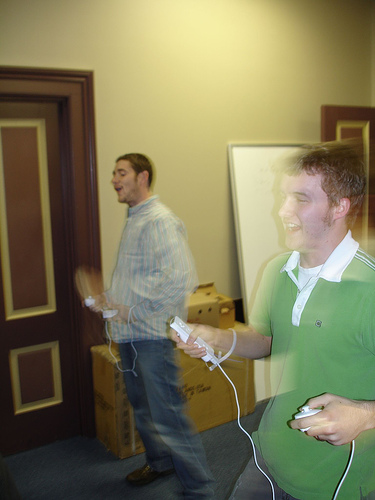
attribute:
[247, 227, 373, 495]
polo shirt — green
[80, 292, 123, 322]
controller — Wii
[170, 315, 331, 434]
controller — Wii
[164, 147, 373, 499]
man — young, smiling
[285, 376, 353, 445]
controller — wii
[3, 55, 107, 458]
door — interior , Dark colored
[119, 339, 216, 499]
jeans — blue, denim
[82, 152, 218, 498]
man — young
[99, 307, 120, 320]
controller — wii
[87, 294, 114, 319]
controller — Wii, joystick